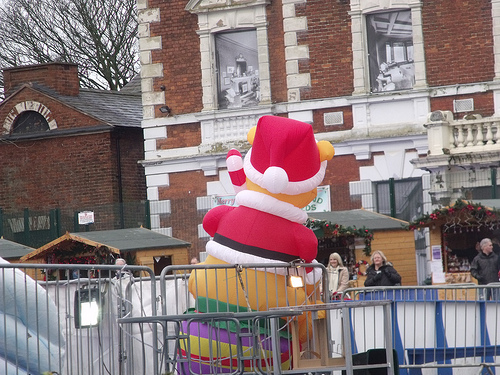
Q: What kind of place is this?
A: It is a street.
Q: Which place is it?
A: It is a street.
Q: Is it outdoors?
A: Yes, it is outdoors.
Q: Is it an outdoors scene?
A: Yes, it is outdoors.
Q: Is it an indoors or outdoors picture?
A: It is outdoors.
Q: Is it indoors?
A: No, it is outdoors.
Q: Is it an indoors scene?
A: No, it is outdoors.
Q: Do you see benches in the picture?
A: No, there are no benches.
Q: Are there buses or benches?
A: No, there are no benches or buses.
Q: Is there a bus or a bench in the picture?
A: No, there are no benches or buses.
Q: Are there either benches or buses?
A: No, there are no benches or buses.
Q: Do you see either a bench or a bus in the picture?
A: No, there are no benches or buses.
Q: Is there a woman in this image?
A: Yes, there is a woman.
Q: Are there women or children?
A: Yes, there is a woman.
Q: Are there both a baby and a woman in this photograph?
A: No, there is a woman but no babies.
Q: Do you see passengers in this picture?
A: No, there are no passengers.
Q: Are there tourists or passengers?
A: No, there are no passengers or tourists.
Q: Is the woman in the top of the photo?
A: No, the woman is in the bottom of the image.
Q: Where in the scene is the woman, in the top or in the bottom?
A: The woman is in the bottom of the image.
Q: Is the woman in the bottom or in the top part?
A: The woman is in the bottom of the image.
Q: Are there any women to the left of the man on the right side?
A: Yes, there is a woman to the left of the man.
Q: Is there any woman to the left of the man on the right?
A: Yes, there is a woman to the left of the man.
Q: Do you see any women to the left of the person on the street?
A: Yes, there is a woman to the left of the man.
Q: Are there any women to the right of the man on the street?
A: No, the woman is to the left of the man.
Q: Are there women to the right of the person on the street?
A: No, the woman is to the left of the man.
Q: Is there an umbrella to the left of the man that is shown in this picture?
A: No, there is a woman to the left of the man.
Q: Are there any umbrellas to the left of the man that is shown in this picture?
A: No, there is a woman to the left of the man.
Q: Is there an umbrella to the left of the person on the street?
A: No, there is a woman to the left of the man.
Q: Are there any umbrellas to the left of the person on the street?
A: No, there is a woman to the left of the man.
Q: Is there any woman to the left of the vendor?
A: Yes, there is a woman to the left of the vendor.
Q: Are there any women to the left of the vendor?
A: Yes, there is a woman to the left of the vendor.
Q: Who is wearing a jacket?
A: The woman is wearing a jacket.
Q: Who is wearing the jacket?
A: The woman is wearing a jacket.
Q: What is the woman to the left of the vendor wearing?
A: The woman is wearing a jacket.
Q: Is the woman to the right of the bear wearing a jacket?
A: Yes, the woman is wearing a jacket.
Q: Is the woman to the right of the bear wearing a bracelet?
A: No, the woman is wearing a jacket.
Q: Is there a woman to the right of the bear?
A: Yes, there is a woman to the right of the bear.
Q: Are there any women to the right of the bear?
A: Yes, there is a woman to the right of the bear.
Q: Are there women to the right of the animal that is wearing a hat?
A: Yes, there is a woman to the right of the bear.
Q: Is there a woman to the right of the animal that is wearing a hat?
A: Yes, there is a woman to the right of the bear.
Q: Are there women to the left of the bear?
A: No, the woman is to the right of the bear.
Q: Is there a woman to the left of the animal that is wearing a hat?
A: No, the woman is to the right of the bear.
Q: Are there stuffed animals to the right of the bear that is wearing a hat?
A: No, there is a woman to the right of the bear.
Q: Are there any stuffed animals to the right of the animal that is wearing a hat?
A: No, there is a woman to the right of the bear.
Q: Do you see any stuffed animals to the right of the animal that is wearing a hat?
A: No, there is a woman to the right of the bear.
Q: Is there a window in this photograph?
A: Yes, there is a window.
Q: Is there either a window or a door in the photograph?
A: Yes, there is a window.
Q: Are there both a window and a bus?
A: No, there is a window but no buses.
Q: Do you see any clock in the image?
A: No, there are no clocks.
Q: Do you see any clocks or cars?
A: No, there are no clocks or cars.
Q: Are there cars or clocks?
A: No, there are no clocks or cars.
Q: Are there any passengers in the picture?
A: No, there are no passengers.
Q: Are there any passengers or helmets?
A: No, there are no passengers or helmets.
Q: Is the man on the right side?
A: Yes, the man is on the right of the image.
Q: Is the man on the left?
A: No, the man is on the right of the image.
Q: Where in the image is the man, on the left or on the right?
A: The man is on the right of the image.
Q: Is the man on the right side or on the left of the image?
A: The man is on the right of the image.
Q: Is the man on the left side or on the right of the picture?
A: The man is on the right of the image.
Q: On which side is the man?
A: The man is on the right of the image.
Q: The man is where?
A: The man is on the street.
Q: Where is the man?
A: The man is on the street.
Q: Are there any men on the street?
A: Yes, there is a man on the street.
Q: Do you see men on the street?
A: Yes, there is a man on the street.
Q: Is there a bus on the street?
A: No, there is a man on the street.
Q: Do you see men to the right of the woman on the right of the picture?
A: Yes, there is a man to the right of the woman.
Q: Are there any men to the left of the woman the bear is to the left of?
A: No, the man is to the right of the woman.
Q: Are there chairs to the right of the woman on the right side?
A: No, there is a man to the right of the woman.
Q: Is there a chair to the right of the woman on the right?
A: No, there is a man to the right of the woman.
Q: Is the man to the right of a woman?
A: Yes, the man is to the right of a woman.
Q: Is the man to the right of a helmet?
A: No, the man is to the right of a woman.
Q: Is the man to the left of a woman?
A: No, the man is to the right of a woman.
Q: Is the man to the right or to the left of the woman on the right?
A: The man is to the right of the woman.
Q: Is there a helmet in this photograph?
A: No, there are no helmets.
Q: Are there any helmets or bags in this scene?
A: No, there are no helmets or bags.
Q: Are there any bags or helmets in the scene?
A: No, there are no helmets or bags.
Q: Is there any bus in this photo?
A: No, there are no buses.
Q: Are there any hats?
A: Yes, there is a hat.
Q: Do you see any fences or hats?
A: Yes, there is a hat.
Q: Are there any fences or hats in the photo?
A: Yes, there is a hat.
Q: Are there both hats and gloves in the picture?
A: No, there is a hat but no gloves.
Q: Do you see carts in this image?
A: No, there are no carts.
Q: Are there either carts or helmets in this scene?
A: No, there are no carts or helmets.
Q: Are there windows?
A: Yes, there is a window.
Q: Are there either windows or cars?
A: Yes, there is a window.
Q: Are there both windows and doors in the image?
A: No, there is a window but no doors.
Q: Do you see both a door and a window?
A: No, there is a window but no doors.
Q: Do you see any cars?
A: No, there are no cars.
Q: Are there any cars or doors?
A: No, there are no cars or doors.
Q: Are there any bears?
A: Yes, there is a bear.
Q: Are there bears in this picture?
A: Yes, there is a bear.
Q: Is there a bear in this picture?
A: Yes, there is a bear.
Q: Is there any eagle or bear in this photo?
A: Yes, there is a bear.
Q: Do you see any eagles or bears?
A: Yes, there is a bear.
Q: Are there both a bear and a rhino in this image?
A: No, there is a bear but no rhinos.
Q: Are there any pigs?
A: No, there are no pigs.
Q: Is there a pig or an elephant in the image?
A: No, there are no pigs or elephants.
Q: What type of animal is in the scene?
A: The animal is a bear.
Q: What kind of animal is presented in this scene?
A: The animal is a bear.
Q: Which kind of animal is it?
A: The animal is a bear.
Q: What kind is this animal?
A: This is a bear.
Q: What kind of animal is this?
A: This is a bear.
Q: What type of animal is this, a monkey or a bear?
A: This is a bear.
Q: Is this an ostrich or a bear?
A: This is a bear.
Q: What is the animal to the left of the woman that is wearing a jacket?
A: The animal is a bear.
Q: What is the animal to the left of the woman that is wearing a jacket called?
A: The animal is a bear.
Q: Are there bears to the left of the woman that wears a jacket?
A: Yes, there is a bear to the left of the woman.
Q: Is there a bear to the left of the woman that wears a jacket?
A: Yes, there is a bear to the left of the woman.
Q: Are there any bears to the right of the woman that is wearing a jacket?
A: No, the bear is to the left of the woman.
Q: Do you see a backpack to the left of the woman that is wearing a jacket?
A: No, there is a bear to the left of the woman.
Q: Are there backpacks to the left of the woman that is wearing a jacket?
A: No, there is a bear to the left of the woman.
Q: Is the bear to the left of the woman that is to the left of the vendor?
A: Yes, the bear is to the left of the woman.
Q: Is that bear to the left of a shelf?
A: No, the bear is to the left of the woman.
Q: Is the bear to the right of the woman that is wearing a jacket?
A: No, the bear is to the left of the woman.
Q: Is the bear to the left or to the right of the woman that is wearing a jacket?
A: The bear is to the left of the woman.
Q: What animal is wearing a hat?
A: The bear is wearing a hat.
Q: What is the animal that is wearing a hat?
A: The animal is a bear.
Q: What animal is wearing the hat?
A: The animal is a bear.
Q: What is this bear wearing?
A: The bear is wearing a hat.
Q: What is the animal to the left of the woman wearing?
A: The bear is wearing a hat.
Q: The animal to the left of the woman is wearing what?
A: The bear is wearing a hat.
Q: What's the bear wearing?
A: The bear is wearing a hat.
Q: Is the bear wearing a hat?
A: Yes, the bear is wearing a hat.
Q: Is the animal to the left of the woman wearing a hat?
A: Yes, the bear is wearing a hat.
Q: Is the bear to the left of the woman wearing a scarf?
A: No, the bear is wearing a hat.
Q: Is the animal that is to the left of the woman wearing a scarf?
A: No, the bear is wearing a hat.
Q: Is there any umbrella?
A: No, there are no umbrellas.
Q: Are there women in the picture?
A: Yes, there is a woman.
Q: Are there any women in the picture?
A: Yes, there is a woman.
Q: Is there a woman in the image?
A: Yes, there is a woman.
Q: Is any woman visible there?
A: Yes, there is a woman.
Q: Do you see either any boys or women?
A: Yes, there is a woman.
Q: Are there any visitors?
A: No, there are no visitors.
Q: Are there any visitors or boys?
A: No, there are no visitors or boys.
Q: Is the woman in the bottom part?
A: Yes, the woman is in the bottom of the image.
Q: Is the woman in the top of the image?
A: No, the woman is in the bottom of the image.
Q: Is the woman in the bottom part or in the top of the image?
A: The woman is in the bottom of the image.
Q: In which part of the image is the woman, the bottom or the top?
A: The woman is in the bottom of the image.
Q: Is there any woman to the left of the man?
A: Yes, there is a woman to the left of the man.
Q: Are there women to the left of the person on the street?
A: Yes, there is a woman to the left of the man.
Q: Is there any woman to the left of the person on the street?
A: Yes, there is a woman to the left of the man.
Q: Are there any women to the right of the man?
A: No, the woman is to the left of the man.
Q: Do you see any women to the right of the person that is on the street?
A: No, the woman is to the left of the man.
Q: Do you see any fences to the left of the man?
A: No, there is a woman to the left of the man.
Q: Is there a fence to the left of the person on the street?
A: No, there is a woman to the left of the man.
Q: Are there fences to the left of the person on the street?
A: No, there is a woman to the left of the man.